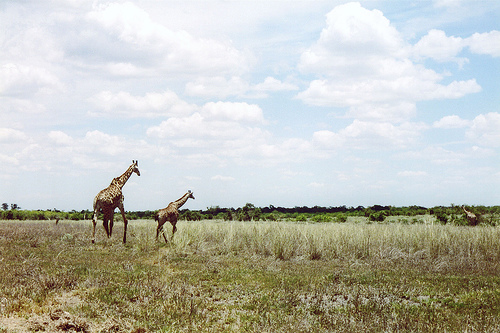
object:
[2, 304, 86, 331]
sandy soil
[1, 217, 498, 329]
grassy plain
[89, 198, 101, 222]
tail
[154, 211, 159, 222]
tail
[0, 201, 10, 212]
trees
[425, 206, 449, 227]
trees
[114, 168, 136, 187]
neck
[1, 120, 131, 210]
clouds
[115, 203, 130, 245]
leg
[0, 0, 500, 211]
sky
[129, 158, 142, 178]
head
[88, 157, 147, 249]
giraffe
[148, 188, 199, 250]
giraffe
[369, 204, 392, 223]
tree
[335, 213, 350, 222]
tree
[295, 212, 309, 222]
tree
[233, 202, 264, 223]
tree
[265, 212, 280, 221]
tree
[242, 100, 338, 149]
section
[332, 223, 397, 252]
section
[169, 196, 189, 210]
neck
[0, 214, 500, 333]
grass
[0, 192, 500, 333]
plantation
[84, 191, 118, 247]
back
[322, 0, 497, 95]
cloud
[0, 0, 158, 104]
cloud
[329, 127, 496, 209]
cloud